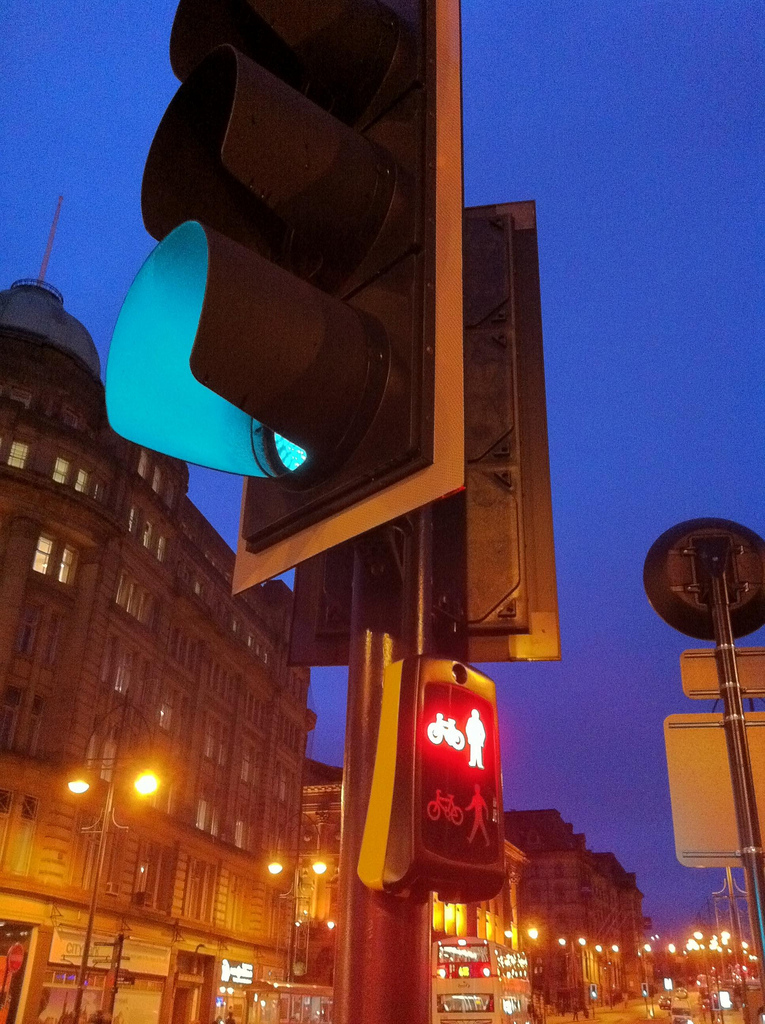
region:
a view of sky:
[596, 156, 653, 227]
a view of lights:
[512, 932, 639, 981]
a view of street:
[526, 867, 750, 994]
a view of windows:
[199, 793, 271, 878]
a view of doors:
[387, 881, 519, 1014]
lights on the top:
[55, 696, 194, 838]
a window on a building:
[8, 428, 26, 476]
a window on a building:
[49, 449, 66, 483]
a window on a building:
[18, 520, 50, 585]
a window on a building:
[60, 536, 78, 584]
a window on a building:
[75, 458, 92, 491]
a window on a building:
[112, 489, 137, 530]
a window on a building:
[122, 834, 156, 909]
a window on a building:
[182, 782, 218, 836]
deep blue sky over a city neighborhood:
[12, 12, 761, 1015]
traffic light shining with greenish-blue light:
[106, 5, 472, 587]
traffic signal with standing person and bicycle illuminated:
[355, 651, 509, 904]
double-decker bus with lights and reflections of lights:
[428, 931, 534, 1020]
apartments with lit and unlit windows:
[7, 321, 322, 940]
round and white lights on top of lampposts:
[498, 918, 761, 1019]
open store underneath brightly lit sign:
[204, 954, 255, 1020]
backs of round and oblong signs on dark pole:
[639, 513, 760, 938]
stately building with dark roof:
[508, 803, 647, 1016]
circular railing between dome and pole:
[5, 189, 104, 381]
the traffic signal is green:
[109, 2, 469, 577]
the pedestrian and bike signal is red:
[356, 652, 508, 912]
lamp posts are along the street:
[20, 742, 762, 1021]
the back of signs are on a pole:
[636, 512, 763, 921]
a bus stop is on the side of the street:
[238, 976, 334, 1021]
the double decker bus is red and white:
[430, 929, 531, 1021]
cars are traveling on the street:
[649, 980, 703, 1021]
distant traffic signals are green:
[583, 978, 655, 1006]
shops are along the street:
[1, 911, 335, 1021]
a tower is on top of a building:
[4, 189, 303, 1021]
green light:
[103, 239, 302, 482]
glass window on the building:
[49, 455, 65, 484]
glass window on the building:
[71, 467, 86, 495]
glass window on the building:
[137, 516, 144, 552]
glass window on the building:
[54, 542, 72, 588]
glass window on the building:
[191, 787, 208, 836]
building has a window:
[113, 644, 131, 696]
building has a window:
[113, 574, 128, 607]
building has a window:
[56, 539, 75, 578]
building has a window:
[30, 529, 52, 571]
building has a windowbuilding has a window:
[67, 463, 85, 492]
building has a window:
[152, 464, 161, 490]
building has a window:
[138, 447, 148, 479]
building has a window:
[59, 545, 76, 581]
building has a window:
[31, 535, 57, 574]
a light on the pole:
[122, 718, 206, 881]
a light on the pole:
[67, 749, 119, 821]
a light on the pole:
[289, 820, 372, 926]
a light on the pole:
[244, 820, 299, 899]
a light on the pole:
[407, 875, 452, 931]